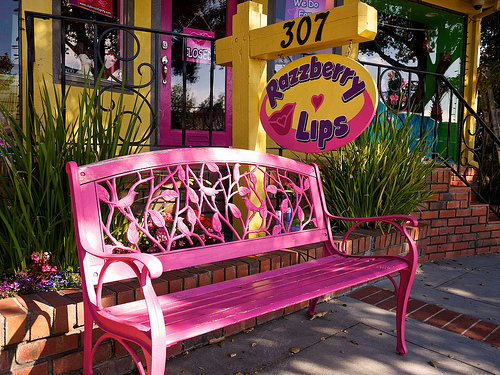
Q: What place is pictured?
A: It is a garden.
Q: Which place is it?
A: It is a garden.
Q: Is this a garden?
A: Yes, it is a garden.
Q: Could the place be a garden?
A: Yes, it is a garden.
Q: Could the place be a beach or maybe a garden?
A: It is a garden.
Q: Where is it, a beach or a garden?
A: It is a garden.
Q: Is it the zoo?
A: No, it is the garden.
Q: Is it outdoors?
A: Yes, it is outdoors.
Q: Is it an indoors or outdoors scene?
A: It is outdoors.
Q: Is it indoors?
A: No, it is outdoors.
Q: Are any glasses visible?
A: No, there are no glasses.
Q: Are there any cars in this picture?
A: No, there are no cars.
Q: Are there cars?
A: No, there are no cars.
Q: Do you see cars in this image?
A: No, there are no cars.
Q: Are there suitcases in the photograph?
A: No, there are no suitcases.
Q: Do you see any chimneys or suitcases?
A: No, there are no suitcases or chimneys.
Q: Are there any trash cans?
A: No, there are no trash cans.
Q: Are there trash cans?
A: No, there are no trash cans.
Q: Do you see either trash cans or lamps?
A: No, there are no trash cans or lamps.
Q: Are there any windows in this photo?
A: Yes, there is a window.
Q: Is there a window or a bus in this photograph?
A: Yes, there is a window.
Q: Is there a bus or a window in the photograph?
A: Yes, there is a window.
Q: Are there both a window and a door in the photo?
A: Yes, there are both a window and a door.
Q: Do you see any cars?
A: No, there are no cars.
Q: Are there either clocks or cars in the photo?
A: No, there are no cars or clocks.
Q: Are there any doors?
A: Yes, there is a door.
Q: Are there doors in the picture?
A: Yes, there is a door.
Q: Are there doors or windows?
A: Yes, there is a door.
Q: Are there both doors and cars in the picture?
A: No, there is a door but no cars.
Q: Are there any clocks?
A: No, there are no clocks.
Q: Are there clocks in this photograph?
A: No, there are no clocks.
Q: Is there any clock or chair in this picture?
A: No, there are no clocks or chairs.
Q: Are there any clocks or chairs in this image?
A: No, there are no clocks or chairs.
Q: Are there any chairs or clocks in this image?
A: No, there are no clocks or chairs.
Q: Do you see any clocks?
A: No, there are no clocks.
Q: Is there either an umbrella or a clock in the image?
A: No, there are no clocks or umbrellas.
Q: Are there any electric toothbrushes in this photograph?
A: No, there are no electric toothbrushes.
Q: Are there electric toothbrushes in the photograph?
A: No, there are no electric toothbrushes.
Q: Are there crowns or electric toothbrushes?
A: No, there are no electric toothbrushes or crowns.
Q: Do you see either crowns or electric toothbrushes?
A: No, there are no electric toothbrushes or crowns.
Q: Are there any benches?
A: Yes, there is a bench.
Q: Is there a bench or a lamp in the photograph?
A: Yes, there is a bench.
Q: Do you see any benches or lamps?
A: Yes, there is a bench.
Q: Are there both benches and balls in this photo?
A: No, there is a bench but no balls.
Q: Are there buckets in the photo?
A: No, there are no buckets.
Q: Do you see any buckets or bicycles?
A: No, there are no buckets or bicycles.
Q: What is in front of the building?
A: The bench is in front of the building.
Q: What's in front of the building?
A: The bench is in front of the building.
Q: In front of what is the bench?
A: The bench is in front of the building.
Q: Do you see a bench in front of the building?
A: Yes, there is a bench in front of the building.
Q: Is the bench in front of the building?
A: Yes, the bench is in front of the building.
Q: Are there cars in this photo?
A: No, there are no cars.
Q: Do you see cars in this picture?
A: No, there are no cars.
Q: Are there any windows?
A: Yes, there is a window.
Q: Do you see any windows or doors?
A: Yes, there is a window.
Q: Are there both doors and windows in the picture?
A: Yes, there are both a window and a door.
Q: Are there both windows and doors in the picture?
A: Yes, there are both a window and a door.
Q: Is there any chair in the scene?
A: No, there are no chairs.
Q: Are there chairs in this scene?
A: No, there are no chairs.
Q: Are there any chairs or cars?
A: No, there are no chairs or cars.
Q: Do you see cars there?
A: No, there are no cars.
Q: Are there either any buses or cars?
A: No, there are no cars or buses.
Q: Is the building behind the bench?
A: Yes, the building is behind the bench.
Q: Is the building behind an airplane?
A: No, the building is behind the bench.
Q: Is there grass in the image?
A: Yes, there is grass.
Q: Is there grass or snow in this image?
A: Yes, there is grass.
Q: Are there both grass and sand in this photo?
A: No, there is grass but no sand.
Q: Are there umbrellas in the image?
A: No, there are no umbrellas.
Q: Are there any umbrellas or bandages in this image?
A: No, there are no umbrellas or bandages.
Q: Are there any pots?
A: No, there are no pots.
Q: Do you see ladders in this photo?
A: No, there are no ladders.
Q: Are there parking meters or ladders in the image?
A: No, there are no ladders or parking meters.